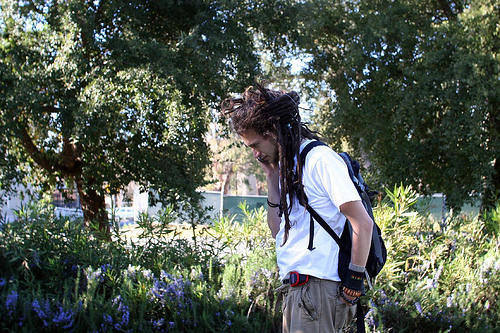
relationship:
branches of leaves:
[2, 1, 499, 212] [123, 104, 206, 196]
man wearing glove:
[211, 79, 397, 331] [339, 255, 371, 307]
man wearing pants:
[227, 79, 373, 333] [259, 272, 359, 330]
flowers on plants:
[0, 180, 500, 333] [16, 212, 278, 326]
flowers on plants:
[26, 295, 75, 329] [16, 212, 278, 326]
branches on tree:
[2, 4, 260, 182] [2, 3, 264, 241]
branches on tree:
[2, 1, 499, 212] [2, 3, 264, 241]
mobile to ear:
[255, 154, 267, 168] [262, 134, 282, 147]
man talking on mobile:
[227, 79, 373, 333] [257, 154, 268, 163]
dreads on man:
[218, 81, 325, 246] [227, 79, 373, 333]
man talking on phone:
[227, 79, 373, 333] [253, 156, 280, 174]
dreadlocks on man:
[277, 87, 309, 245] [227, 79, 373, 333]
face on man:
[238, 130, 270, 167] [227, 79, 373, 333]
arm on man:
[259, 162, 288, 236] [225, 87, 397, 329]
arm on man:
[350, 210, 387, 262] [227, 79, 373, 333]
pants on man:
[275, 273, 349, 328] [225, 87, 397, 329]